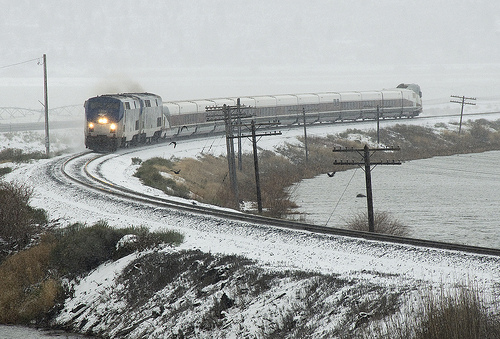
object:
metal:
[69, 173, 93, 185]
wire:
[0, 53, 47, 72]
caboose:
[397, 82, 425, 119]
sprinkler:
[29, 99, 45, 123]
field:
[0, 127, 86, 178]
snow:
[0, 157, 499, 307]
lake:
[278, 147, 500, 251]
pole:
[456, 95, 465, 135]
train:
[83, 83, 426, 154]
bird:
[327, 169, 338, 177]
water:
[0, 322, 95, 338]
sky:
[0, 1, 500, 79]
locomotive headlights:
[108, 123, 121, 132]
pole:
[42, 54, 50, 153]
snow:
[94, 233, 380, 327]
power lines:
[324, 156, 363, 227]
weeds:
[349, 276, 498, 338]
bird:
[171, 169, 183, 175]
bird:
[169, 139, 179, 149]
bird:
[179, 122, 191, 134]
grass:
[0, 219, 185, 324]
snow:
[224, 239, 306, 274]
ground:
[0, 149, 500, 305]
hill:
[47, 242, 485, 335]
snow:
[426, 207, 473, 237]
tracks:
[46, 110, 500, 257]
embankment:
[134, 117, 500, 219]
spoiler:
[388, 75, 438, 104]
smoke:
[95, 72, 150, 94]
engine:
[83, 91, 166, 156]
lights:
[96, 117, 109, 126]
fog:
[0, 0, 500, 153]